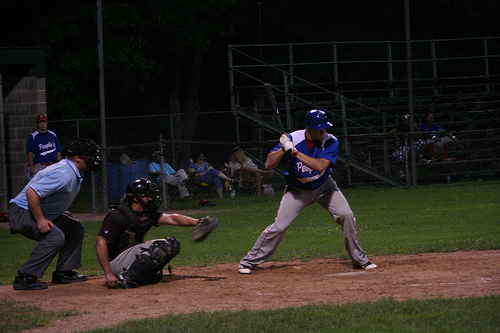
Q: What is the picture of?
A: A baseball field.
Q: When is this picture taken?
A: Evening.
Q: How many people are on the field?
A: Three.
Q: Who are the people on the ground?
A: Two players and one referee.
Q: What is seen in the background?
A: Spectators sitting and watching.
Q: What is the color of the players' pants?
A: Grey.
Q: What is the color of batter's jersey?
A: Blue and white.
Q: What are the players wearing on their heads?
A: Baseball caps.